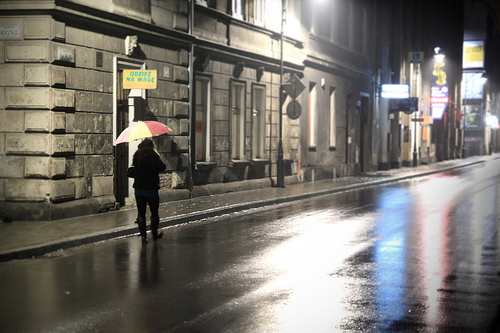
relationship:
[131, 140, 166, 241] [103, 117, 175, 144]
woman carrying umbrella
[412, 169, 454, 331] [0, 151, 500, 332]
reflection of neon lights on pavement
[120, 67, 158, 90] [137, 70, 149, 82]
sign with writing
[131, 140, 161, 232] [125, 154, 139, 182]
woman carrying handbag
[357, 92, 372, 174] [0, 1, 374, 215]
door to building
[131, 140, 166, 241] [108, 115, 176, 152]
woman with umbrella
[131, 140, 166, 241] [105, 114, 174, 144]
woman with umbrella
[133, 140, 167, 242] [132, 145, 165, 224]
person in clothing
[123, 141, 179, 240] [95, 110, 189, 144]
person with umbrella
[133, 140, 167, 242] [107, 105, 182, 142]
person carrying umbrella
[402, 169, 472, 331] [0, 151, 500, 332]
reflection on pavement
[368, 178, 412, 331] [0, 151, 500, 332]
reflection on pavement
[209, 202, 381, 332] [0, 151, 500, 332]
reflection on pavement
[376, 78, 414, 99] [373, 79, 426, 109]
sign with light